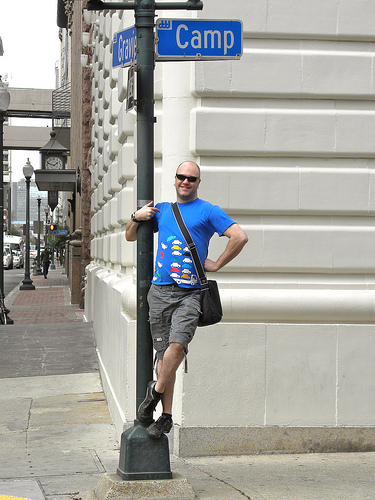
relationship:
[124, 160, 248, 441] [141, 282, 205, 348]
man wears shorts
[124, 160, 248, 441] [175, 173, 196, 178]
man wears sunglasses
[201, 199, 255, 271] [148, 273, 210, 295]
arm on waist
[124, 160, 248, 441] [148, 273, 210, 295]
man has waist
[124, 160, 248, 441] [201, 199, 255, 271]
man has arm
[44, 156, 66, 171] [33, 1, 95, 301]
clock on building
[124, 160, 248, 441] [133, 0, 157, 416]
man on pole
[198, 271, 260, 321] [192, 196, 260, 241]
bag on shoulder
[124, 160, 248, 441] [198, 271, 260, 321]
man holds bag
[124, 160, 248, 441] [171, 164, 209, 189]
man wears sunglasses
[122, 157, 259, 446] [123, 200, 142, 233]
man wears watch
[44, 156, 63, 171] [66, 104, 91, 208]
clock on wall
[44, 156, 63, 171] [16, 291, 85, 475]
clock above sidewalk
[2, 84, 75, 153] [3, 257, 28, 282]
walkways aver street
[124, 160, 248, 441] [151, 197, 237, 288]
man wears t-shirt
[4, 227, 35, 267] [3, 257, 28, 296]
traffic on street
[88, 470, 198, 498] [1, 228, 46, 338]
podium on street